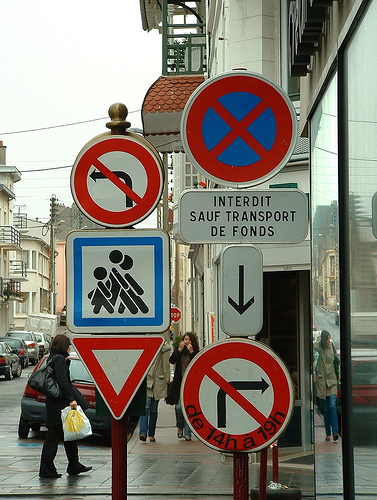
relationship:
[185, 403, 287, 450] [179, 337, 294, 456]
writing on a sign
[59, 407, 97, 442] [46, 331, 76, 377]
plastic bag with person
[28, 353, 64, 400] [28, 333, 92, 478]
shoulder bag on person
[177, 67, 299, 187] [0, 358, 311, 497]
sign on street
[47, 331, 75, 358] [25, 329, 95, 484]
head on person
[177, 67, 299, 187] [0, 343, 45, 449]
sign on street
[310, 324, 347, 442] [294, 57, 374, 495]
reflection on glass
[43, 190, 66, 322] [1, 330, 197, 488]
telephone pole on street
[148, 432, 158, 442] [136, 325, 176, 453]
foot on person